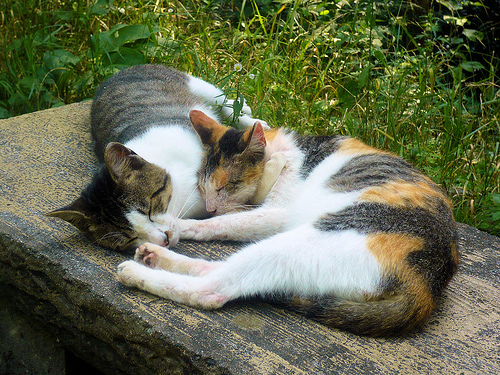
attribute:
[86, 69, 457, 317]
cats — sleeping, asleep, grey, orange, white, resting, striped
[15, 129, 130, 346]
bench — wooden, grey, brown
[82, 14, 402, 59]
vegetation — green, tall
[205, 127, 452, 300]
cat — sleeping, orange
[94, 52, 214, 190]
cat — sleeping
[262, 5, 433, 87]
weeds — green